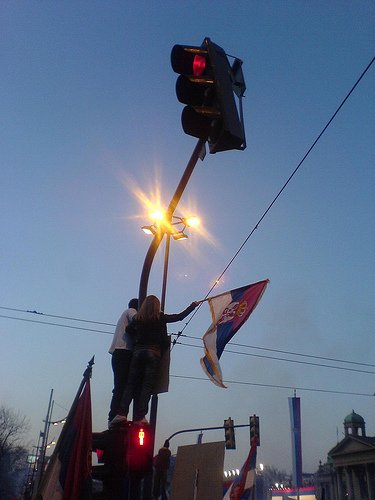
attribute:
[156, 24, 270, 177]
light — traffic, shaped, red, night, street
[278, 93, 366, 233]
cable — air, power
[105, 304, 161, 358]
shirt — white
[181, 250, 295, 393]
pole — flag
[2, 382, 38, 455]
tree — leave, several, growing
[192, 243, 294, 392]
flag — held, waving, holding, air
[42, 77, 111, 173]
sky — blue, large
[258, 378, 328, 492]
building — tall, background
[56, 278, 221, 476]
people — group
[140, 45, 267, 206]
signal — traffic, lit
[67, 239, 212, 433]
woman — waving, standing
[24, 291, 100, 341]
line — power